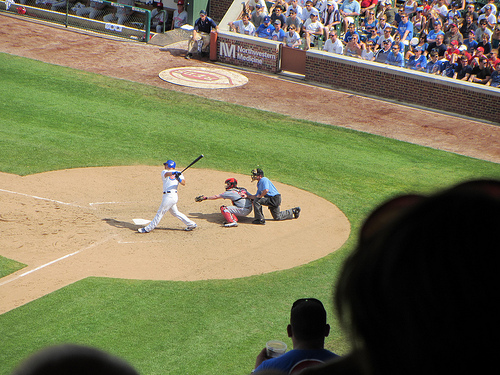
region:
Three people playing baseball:
[138, 149, 310, 237]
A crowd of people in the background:
[221, 3, 498, 108]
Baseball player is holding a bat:
[128, 137, 205, 242]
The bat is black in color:
[173, 150, 206, 184]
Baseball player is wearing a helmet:
[159, 153, 183, 173]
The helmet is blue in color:
[156, 149, 179, 177]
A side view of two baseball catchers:
[190, 157, 306, 232]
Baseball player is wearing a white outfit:
[138, 164, 198, 234]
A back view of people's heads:
[206, 172, 495, 374]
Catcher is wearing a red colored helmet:
[216, 172, 249, 194]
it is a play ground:
[23, 77, 339, 288]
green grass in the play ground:
[12, 72, 110, 136]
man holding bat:
[160, 156, 204, 178]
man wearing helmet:
[206, 176, 258, 189]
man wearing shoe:
[124, 215, 201, 242]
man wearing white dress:
[130, 153, 197, 250]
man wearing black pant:
[254, 186, 304, 228]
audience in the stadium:
[279, 8, 480, 49]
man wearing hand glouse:
[166, 167, 186, 184]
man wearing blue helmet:
[158, 146, 182, 168]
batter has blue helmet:
[160, 159, 176, 173]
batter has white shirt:
[158, 167, 188, 197]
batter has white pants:
[140, 192, 195, 227]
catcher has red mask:
[207, 171, 237, 191]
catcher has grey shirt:
[227, 184, 247, 206]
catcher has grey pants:
[226, 204, 257, 229]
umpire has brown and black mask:
[247, 162, 264, 182]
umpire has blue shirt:
[256, 176, 278, 194]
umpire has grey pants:
[250, 190, 287, 222]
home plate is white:
[131, 195, 155, 235]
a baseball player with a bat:
[135, 150, 201, 233]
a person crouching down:
[193, 175, 251, 226]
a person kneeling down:
[248, 161, 299, 222]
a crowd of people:
[228, 0, 498, 87]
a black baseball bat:
[178, 152, 203, 173]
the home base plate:
[130, 215, 147, 223]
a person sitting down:
[185, 7, 216, 58]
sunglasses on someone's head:
[356, 171, 496, 238]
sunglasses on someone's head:
[290, 295, 320, 306]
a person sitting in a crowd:
[256, 295, 342, 373]